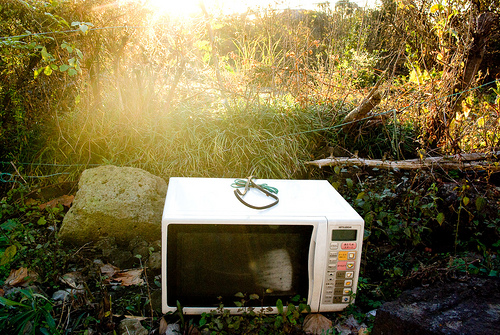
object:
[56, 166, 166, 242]
rock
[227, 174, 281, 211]
cord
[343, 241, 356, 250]
buttons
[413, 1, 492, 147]
trees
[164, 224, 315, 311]
window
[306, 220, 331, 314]
handle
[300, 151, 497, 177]
stick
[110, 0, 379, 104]
sun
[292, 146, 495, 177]
tree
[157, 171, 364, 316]
microwave